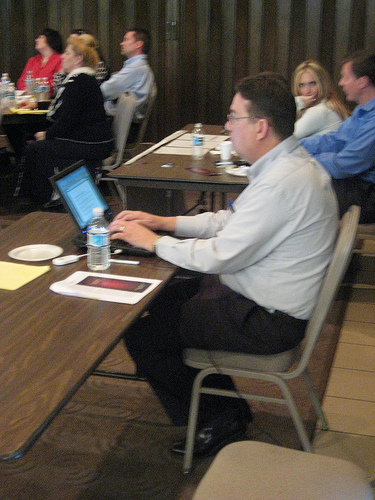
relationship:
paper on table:
[51, 270, 157, 306] [0, 211, 144, 461]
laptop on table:
[55, 156, 145, 249] [0, 211, 144, 461]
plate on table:
[21, 243, 62, 271] [0, 211, 144, 461]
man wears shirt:
[151, 81, 330, 465] [207, 163, 324, 317]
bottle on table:
[79, 221, 121, 277] [0, 211, 144, 461]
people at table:
[253, 45, 375, 212] [0, 211, 144, 461]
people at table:
[31, 23, 149, 161] [0, 71, 41, 130]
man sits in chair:
[151, 81, 330, 465] [184, 258, 367, 461]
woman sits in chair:
[21, 41, 112, 201] [77, 104, 148, 183]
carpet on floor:
[77, 398, 186, 495] [86, 311, 289, 380]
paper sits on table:
[51, 270, 157, 306] [0, 211, 144, 461]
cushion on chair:
[203, 342, 288, 395] [184, 258, 367, 461]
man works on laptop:
[151, 81, 330, 465] [55, 156, 145, 249]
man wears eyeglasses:
[151, 81, 330, 465] [223, 110, 272, 127]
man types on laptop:
[151, 81, 330, 465] [55, 156, 145, 249]